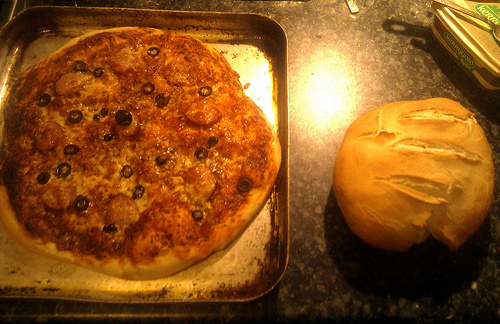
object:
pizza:
[0, 26, 281, 280]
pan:
[3, 5, 291, 304]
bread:
[333, 97, 495, 252]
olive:
[92, 66, 107, 78]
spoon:
[437, 0, 499, 40]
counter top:
[1, 0, 498, 99]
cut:
[375, 171, 462, 206]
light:
[291, 43, 361, 137]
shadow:
[381, 18, 495, 126]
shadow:
[2, 235, 73, 280]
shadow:
[323, 188, 491, 306]